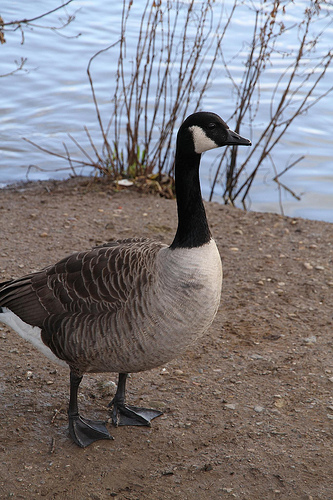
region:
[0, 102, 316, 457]
a bird stands at the edge of the water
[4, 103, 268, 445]
a bird with webbed feet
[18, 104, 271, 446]
a goose standing on the soil beside a body of water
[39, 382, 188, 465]
the feet of the bird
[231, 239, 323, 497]
the sandy ground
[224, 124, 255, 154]
beak of the bird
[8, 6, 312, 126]
a body of water in the background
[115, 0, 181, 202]
vegetation grows at the waters edge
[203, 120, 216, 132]
eye of the bird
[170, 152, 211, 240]
the neck of the bird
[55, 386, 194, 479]
The bird has webbed feet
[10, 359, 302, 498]
The bird is standing in the dirt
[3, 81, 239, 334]
This is a goose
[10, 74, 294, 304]
The goose is by the ponds edge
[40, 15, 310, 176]
Pond sticks grow near the edge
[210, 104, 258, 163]
The goose has a black bill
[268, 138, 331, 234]
There is a reflection in the water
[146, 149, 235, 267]
The gooses neck is black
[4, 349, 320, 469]
not many rocks are present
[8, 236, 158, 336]
The gooses back is made of black feathers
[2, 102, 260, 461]
wild goose beside a lake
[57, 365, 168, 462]
black webbed feet of a goose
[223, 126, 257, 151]
black beak of a goose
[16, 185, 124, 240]
dirt and sand of lakeside beach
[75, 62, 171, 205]
reeds growing beside a lake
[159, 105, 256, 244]
head and neck of a wild goose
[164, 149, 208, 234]
black long goose neck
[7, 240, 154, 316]
chocolate brown goose wing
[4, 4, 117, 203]
portion of a fresh water lake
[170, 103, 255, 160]
black and white goose head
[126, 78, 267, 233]
Canadian goose.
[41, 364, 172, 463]
Goose feet.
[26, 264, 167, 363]
Goose wings covered in feathers.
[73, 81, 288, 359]
Goose on the lake side.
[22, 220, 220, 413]
Feathers on the goose.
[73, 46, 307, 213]
Grass along the water.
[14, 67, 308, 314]
Goose in front of the pool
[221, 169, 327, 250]
The lake and goose.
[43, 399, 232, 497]
Goose on the dirt.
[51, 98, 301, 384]
Goose standing by the pond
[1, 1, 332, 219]
the water next to the shore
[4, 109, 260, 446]
the bird standing on the ground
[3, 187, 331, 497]
the ground the bird is standing on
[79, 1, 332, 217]
the tall plant by the water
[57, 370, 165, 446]
the legs of the bird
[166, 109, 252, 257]
the neck and head of the bird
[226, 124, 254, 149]
the beak of the bird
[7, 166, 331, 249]
the edge of the land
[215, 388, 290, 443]
the rocks in the dirt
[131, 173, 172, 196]
leaves of the plant